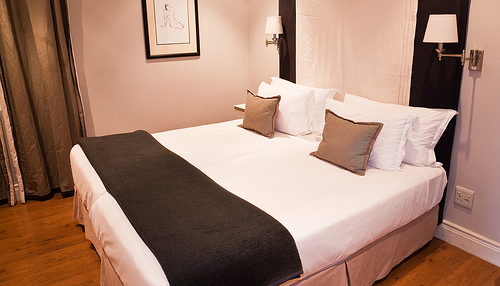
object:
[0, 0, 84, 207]
brown curtain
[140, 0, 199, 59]
picture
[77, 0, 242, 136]
wall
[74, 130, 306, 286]
blanket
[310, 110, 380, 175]
pillow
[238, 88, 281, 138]
pillow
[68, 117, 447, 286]
sheet